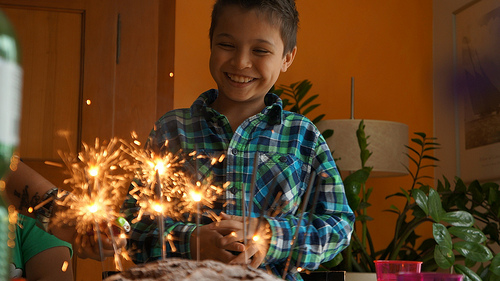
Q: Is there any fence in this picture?
A: No, there are no fences.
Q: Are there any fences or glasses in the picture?
A: No, there are no fences or glasses.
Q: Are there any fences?
A: No, there are no fences.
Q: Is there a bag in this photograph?
A: No, there are no bags.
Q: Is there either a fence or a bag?
A: No, there are no bags or fences.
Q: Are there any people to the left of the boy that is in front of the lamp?
A: Yes, there is a person to the left of the boy.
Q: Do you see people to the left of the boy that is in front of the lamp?
A: Yes, there is a person to the left of the boy.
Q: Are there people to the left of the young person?
A: Yes, there is a person to the left of the boy.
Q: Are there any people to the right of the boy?
A: No, the person is to the left of the boy.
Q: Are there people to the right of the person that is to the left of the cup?
A: No, the person is to the left of the boy.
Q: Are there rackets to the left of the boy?
A: No, there is a person to the left of the boy.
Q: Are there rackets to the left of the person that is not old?
A: No, there is a person to the left of the boy.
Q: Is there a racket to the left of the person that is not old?
A: No, there is a person to the left of the boy.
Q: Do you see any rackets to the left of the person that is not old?
A: No, there is a person to the left of the boy.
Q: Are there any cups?
A: Yes, there is a cup.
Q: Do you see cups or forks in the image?
A: Yes, there is a cup.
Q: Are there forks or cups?
A: Yes, there is a cup.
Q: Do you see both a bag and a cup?
A: No, there is a cup but no bags.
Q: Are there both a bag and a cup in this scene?
A: No, there is a cup but no bags.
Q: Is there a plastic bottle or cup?
A: Yes, there is a plastic cup.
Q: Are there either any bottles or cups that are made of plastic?
A: Yes, the cup is made of plastic.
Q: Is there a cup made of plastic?
A: Yes, there is a cup that is made of plastic.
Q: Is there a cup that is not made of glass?
A: Yes, there is a cup that is made of plastic.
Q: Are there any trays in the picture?
A: No, there are no trays.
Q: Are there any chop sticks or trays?
A: No, there are no trays or chop sticks.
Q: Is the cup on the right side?
A: Yes, the cup is on the right of the image.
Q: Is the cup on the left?
A: No, the cup is on the right of the image.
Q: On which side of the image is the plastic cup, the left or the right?
A: The cup is on the right of the image.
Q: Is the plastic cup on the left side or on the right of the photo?
A: The cup is on the right of the image.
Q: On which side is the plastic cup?
A: The cup is on the right of the image.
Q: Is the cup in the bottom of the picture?
A: Yes, the cup is in the bottom of the image.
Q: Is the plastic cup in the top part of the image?
A: No, the cup is in the bottom of the image.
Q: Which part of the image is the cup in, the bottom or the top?
A: The cup is in the bottom of the image.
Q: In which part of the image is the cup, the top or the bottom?
A: The cup is in the bottom of the image.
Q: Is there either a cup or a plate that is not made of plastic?
A: No, there is a cup but it is made of plastic.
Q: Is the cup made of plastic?
A: Yes, the cup is made of plastic.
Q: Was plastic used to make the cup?
A: Yes, the cup is made of plastic.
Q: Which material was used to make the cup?
A: The cup is made of plastic.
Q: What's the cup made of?
A: The cup is made of plastic.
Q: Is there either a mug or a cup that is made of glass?
A: No, there is a cup but it is made of plastic.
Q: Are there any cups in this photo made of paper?
A: No, there is a cup but it is made of plastic.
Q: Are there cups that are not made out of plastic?
A: No, there is a cup but it is made of plastic.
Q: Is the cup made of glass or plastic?
A: The cup is made of plastic.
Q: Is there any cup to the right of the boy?
A: Yes, there is a cup to the right of the boy.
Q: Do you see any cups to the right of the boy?
A: Yes, there is a cup to the right of the boy.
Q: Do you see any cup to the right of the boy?
A: Yes, there is a cup to the right of the boy.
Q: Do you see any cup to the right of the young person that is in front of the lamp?
A: Yes, there is a cup to the right of the boy.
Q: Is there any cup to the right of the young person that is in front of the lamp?
A: Yes, there is a cup to the right of the boy.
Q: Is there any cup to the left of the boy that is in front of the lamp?
A: No, the cup is to the right of the boy.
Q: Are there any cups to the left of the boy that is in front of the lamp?
A: No, the cup is to the right of the boy.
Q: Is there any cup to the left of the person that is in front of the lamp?
A: No, the cup is to the right of the boy.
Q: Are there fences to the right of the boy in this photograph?
A: No, there is a cup to the right of the boy.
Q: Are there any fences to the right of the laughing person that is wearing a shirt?
A: No, there is a cup to the right of the boy.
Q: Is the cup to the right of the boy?
A: Yes, the cup is to the right of the boy.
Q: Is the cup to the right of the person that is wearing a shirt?
A: Yes, the cup is to the right of the boy.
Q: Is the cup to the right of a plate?
A: No, the cup is to the right of the boy.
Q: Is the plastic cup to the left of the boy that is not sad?
A: No, the cup is to the right of the boy.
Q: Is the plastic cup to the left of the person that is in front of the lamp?
A: No, the cup is to the right of the boy.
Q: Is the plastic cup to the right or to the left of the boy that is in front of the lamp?
A: The cup is to the right of the boy.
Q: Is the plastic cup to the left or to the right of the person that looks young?
A: The cup is to the right of the boy.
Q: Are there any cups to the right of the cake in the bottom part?
A: Yes, there is a cup to the right of the cake.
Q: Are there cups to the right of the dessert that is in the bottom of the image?
A: Yes, there is a cup to the right of the cake.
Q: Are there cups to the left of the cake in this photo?
A: No, the cup is to the right of the cake.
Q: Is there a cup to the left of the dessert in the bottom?
A: No, the cup is to the right of the cake.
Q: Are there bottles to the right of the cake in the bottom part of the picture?
A: No, there is a cup to the right of the cake.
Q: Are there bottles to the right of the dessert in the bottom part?
A: No, there is a cup to the right of the cake.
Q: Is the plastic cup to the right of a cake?
A: Yes, the cup is to the right of a cake.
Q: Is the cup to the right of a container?
A: No, the cup is to the right of a cake.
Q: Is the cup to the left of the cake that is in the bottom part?
A: No, the cup is to the right of the cake.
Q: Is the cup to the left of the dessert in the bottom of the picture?
A: No, the cup is to the right of the cake.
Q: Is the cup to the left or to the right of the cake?
A: The cup is to the right of the cake.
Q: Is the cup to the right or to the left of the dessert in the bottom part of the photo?
A: The cup is to the right of the cake.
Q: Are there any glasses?
A: No, there are no glasses.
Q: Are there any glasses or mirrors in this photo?
A: No, there are no glasses or mirrors.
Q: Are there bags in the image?
A: No, there are no bags.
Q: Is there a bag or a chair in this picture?
A: No, there are no bags or chairs.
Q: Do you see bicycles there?
A: No, there are no bicycles.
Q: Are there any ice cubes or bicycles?
A: No, there are no bicycles or ice cubes.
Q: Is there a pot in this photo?
A: No, there are no pots.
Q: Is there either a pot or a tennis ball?
A: No, there are no pots or tennis balls.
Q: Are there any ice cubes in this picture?
A: No, there are no ice cubes.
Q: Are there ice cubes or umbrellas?
A: No, there are no ice cubes or umbrellas.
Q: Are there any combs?
A: No, there are no combs.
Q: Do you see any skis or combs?
A: No, there are no combs or skis.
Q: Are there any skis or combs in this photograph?
A: No, there are no combs or skis.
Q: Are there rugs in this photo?
A: No, there are no rugs.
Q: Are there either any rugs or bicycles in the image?
A: No, there are no rugs or bicycles.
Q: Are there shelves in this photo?
A: No, there are no shelves.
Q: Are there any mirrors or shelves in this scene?
A: No, there are no shelves or mirrors.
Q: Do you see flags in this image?
A: No, there are no flags.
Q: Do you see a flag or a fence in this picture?
A: No, there are no flags or fences.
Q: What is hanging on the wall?
A: The artwork is hanging on the wall.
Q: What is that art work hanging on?
A: The art work is hanging on the wall.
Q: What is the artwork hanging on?
A: The art work is hanging on the wall.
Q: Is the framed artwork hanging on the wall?
A: Yes, the art work is hanging on the wall.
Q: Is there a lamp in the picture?
A: Yes, there is a lamp.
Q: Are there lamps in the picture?
A: Yes, there is a lamp.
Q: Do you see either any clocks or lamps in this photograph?
A: Yes, there is a lamp.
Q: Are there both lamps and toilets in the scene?
A: No, there is a lamp but no toilets.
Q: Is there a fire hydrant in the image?
A: No, there are no fire hydrants.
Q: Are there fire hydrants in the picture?
A: No, there are no fire hydrants.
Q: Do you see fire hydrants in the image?
A: No, there are no fire hydrants.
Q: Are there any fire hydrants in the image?
A: No, there are no fire hydrants.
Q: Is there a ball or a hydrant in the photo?
A: No, there are no fire hydrants or balls.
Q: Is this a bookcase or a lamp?
A: This is a lamp.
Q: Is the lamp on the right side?
A: Yes, the lamp is on the right of the image.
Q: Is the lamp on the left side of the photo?
A: No, the lamp is on the right of the image.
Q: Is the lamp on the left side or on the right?
A: The lamp is on the right of the image.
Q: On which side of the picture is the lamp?
A: The lamp is on the right of the image.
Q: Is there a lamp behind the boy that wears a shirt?
A: Yes, there is a lamp behind the boy.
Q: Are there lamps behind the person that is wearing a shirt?
A: Yes, there is a lamp behind the boy.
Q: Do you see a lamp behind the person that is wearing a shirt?
A: Yes, there is a lamp behind the boy.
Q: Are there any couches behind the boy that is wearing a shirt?
A: No, there is a lamp behind the boy.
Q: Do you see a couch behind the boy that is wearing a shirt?
A: No, there is a lamp behind the boy.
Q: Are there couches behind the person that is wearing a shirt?
A: No, there is a lamp behind the boy.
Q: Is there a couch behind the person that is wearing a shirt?
A: No, there is a lamp behind the boy.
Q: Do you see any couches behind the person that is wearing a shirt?
A: No, there is a lamp behind the boy.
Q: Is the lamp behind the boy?
A: Yes, the lamp is behind the boy.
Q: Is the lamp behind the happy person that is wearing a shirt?
A: Yes, the lamp is behind the boy.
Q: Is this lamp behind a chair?
A: No, the lamp is behind the boy.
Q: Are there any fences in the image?
A: No, there are no fences.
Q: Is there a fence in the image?
A: No, there are no fences.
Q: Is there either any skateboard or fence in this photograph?
A: No, there are no fences or skateboards.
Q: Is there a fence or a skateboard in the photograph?
A: No, there are no fences or skateboards.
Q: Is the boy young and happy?
A: Yes, the boy is young and happy.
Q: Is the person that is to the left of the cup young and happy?
A: Yes, the boy is young and happy.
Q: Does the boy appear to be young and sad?
A: No, the boy is young but happy.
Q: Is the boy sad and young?
A: No, the boy is young but happy.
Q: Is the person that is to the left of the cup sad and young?
A: No, the boy is young but happy.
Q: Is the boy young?
A: Yes, the boy is young.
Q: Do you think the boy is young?
A: Yes, the boy is young.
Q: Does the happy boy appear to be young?
A: Yes, the boy is young.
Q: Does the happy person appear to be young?
A: Yes, the boy is young.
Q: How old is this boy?
A: The boy is young.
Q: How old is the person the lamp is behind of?
A: The boy is young.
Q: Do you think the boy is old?
A: No, the boy is young.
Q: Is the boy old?
A: No, the boy is young.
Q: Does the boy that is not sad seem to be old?
A: No, the boy is young.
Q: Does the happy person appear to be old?
A: No, the boy is young.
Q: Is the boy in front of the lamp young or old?
A: The boy is young.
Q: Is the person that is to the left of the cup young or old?
A: The boy is young.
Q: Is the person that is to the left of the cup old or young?
A: The boy is young.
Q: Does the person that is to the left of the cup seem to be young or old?
A: The boy is young.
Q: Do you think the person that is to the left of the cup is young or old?
A: The boy is young.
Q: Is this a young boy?
A: Yes, this is a young boy.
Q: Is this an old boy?
A: No, this is a young boy.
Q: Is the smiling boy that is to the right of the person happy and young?
A: Yes, the boy is happy and young.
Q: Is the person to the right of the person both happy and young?
A: Yes, the boy is happy and young.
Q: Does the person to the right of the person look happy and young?
A: Yes, the boy is happy and young.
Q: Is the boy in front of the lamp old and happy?
A: No, the boy is happy but young.